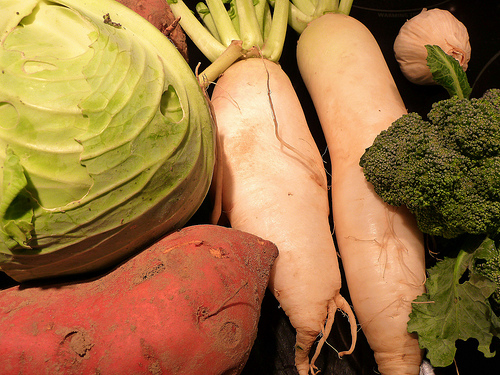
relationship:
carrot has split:
[167, 0, 357, 372] [258, 60, 328, 193]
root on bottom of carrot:
[307, 292, 338, 371] [167, 0, 357, 372]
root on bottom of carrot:
[333, 285, 358, 361] [167, 0, 357, 372]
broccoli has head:
[366, 84, 485, 241] [369, 86, 498, 237]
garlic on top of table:
[389, 6, 474, 91] [474, 19, 485, 33]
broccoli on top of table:
[366, 84, 485, 241] [0, 0, 499, 373]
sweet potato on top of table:
[1, 224, 278, 374] [0, 0, 499, 373]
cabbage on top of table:
[6, 10, 227, 265] [0, 0, 499, 373]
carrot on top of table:
[167, 0, 357, 372] [0, 0, 499, 373]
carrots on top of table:
[294, 0, 442, 373] [0, 0, 499, 373]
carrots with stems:
[201, 13, 442, 373] [162, 8, 357, 61]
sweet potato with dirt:
[1, 224, 278, 374] [70, 330, 92, 355]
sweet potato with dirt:
[1, 224, 278, 374] [148, 361, 163, 373]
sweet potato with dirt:
[1, 224, 278, 374] [98, 348, 109, 362]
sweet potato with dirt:
[1, 224, 278, 374] [188, 352, 205, 366]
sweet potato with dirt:
[1, 224, 278, 374] [254, 268, 268, 285]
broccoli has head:
[366, 84, 485, 241] [373, 93, 485, 206]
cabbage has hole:
[6, 10, 227, 265] [150, 74, 202, 121]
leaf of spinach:
[422, 293, 489, 351] [409, 231, 499, 370]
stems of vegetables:
[162, 8, 286, 62] [229, 68, 349, 327]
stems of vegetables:
[162, 8, 286, 62] [302, 19, 429, 365]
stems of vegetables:
[162, 8, 286, 62] [8, 14, 225, 256]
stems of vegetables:
[162, 8, 286, 62] [3, 220, 284, 373]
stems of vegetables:
[162, 8, 286, 62] [367, 81, 498, 233]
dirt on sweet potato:
[0, 224, 278, 374] [1, 224, 278, 374]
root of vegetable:
[333, 285, 358, 361] [2, 2, 499, 373]